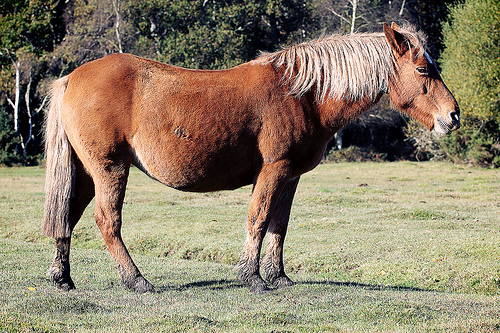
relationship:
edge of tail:
[42, 150, 54, 186] [39, 71, 79, 239]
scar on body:
[171, 122, 202, 144] [61, 58, 318, 186]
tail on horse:
[39, 71, 79, 239] [41, 17, 461, 297]